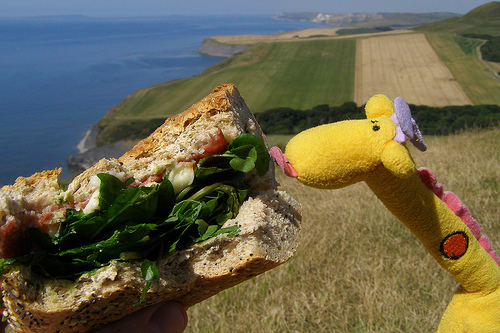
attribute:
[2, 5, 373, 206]
water — blue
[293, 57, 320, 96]
grass — greener, distant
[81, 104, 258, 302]
bread — wheat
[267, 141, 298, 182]
tongue — pink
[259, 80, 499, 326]
toy — stuffed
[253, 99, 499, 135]
trees — distant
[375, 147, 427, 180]
ears — big, hanging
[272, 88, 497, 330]
toy — stuffed, yellow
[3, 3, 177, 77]
water — below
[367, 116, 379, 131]
eyes — black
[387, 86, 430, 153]
hat — purple